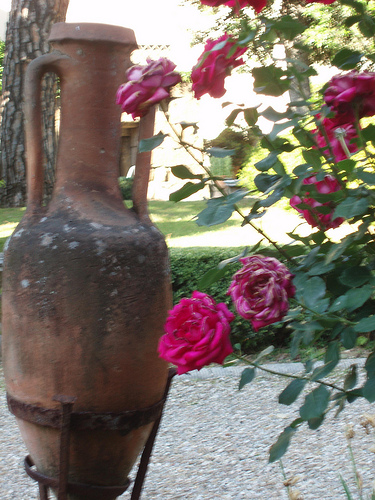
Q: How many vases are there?
A: One.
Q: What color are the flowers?
A: Purple.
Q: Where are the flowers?
A: Next to the vase.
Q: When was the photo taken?
A: Afternoon.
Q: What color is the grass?
A: Green.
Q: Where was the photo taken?
A: Along a sidewalk.